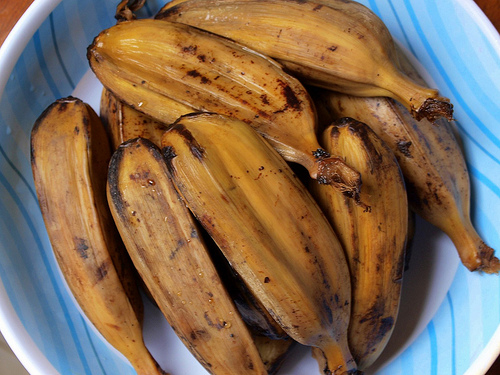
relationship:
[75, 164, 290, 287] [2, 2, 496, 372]
plantains in bowl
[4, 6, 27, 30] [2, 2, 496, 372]
table can be seen above bowl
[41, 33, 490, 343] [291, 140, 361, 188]
bananas have stalk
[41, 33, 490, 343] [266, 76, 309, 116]
bananas have patches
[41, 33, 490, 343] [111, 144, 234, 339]
bananas have peel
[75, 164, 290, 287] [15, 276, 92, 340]
plantains are inside of bowl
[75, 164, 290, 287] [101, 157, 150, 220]
plantains have black spots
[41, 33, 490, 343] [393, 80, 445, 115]
bananas have top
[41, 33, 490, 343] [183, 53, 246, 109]
bananas have brown spot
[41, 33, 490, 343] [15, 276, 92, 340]
bananas inside of bowl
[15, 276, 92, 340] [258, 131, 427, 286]
bowl has fruit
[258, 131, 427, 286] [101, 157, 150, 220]
fruit has black spots